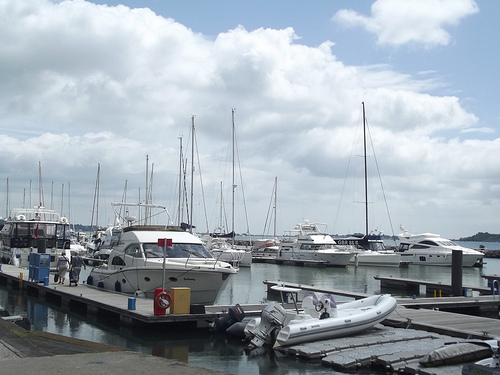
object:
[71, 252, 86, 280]
people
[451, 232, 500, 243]
hill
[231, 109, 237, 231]
masts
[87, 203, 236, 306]
boats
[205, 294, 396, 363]
boat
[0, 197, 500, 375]
harbor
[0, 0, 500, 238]
sky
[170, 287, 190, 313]
box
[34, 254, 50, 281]
boxes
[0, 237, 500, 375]
water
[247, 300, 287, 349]
engine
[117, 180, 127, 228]
sail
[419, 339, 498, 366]
bag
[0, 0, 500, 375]
photo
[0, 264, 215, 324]
birdges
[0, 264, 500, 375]
marina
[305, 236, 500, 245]
shoreline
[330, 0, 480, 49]
clouds